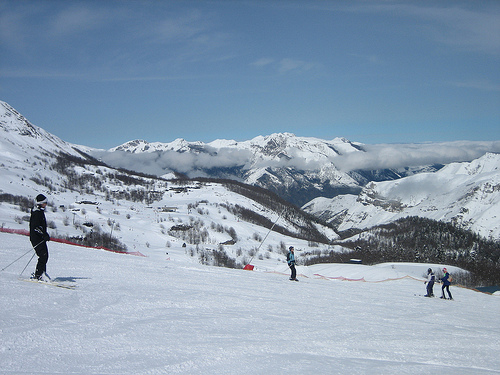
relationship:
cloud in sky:
[0, 0, 499, 152] [2, 4, 498, 140]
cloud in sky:
[8, 9, 98, 52] [2, 4, 498, 140]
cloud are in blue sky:
[0, 0, 499, 152] [0, 1, 499, 151]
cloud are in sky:
[0, 0, 499, 152] [282, 32, 400, 96]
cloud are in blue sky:
[0, 0, 499, 152] [103, 95, 168, 132]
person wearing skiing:
[30, 194, 48, 281] [28, 207, 49, 278]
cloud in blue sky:
[0, 0, 499, 152] [250, 0, 363, 45]